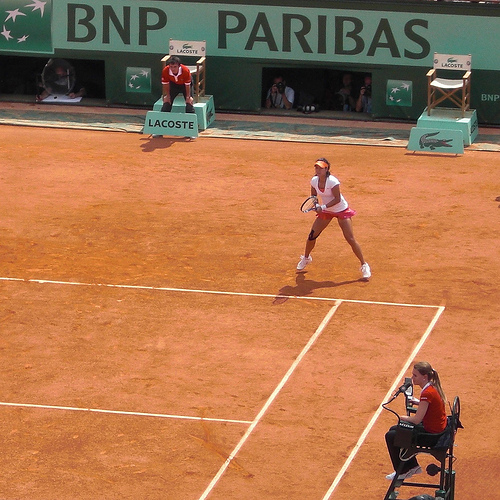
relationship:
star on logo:
[27, 2, 49, 17] [3, 5, 55, 52]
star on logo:
[4, 7, 22, 21] [3, 5, 55, 52]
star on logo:
[13, 35, 33, 45] [3, 5, 55, 52]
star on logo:
[1, 27, 12, 41] [3, 5, 55, 52]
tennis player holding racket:
[295, 157, 371, 280] [297, 195, 322, 213]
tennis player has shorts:
[295, 157, 371, 280] [315, 205, 355, 227]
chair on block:
[423, 47, 475, 113] [407, 99, 484, 154]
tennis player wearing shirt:
[295, 157, 371, 280] [311, 175, 348, 212]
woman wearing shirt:
[379, 357, 461, 482] [407, 384, 445, 436]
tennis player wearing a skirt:
[295, 157, 371, 280] [315, 208, 353, 222]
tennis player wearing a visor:
[295, 157, 371, 280] [312, 155, 324, 167]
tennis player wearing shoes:
[295, 157, 371, 280] [279, 240, 395, 286]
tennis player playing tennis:
[295, 157, 371, 280] [24, 134, 403, 413]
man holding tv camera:
[30, 57, 90, 104] [48, 67, 73, 91]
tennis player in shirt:
[294, 158, 371, 280] [311, 175, 349, 214]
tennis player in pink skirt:
[294, 158, 371, 280] [313, 206, 355, 221]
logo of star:
[0, 1, 58, 60] [23, 0, 49, 18]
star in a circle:
[23, 0, 49, 18] [0, 5, 59, 50]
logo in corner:
[0, 1, 58, 60] [5, 7, 66, 93]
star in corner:
[23, 0, 49, 18] [5, 7, 66, 93]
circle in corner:
[0, 5, 59, 50] [5, 7, 66, 93]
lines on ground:
[287, 285, 454, 343] [152, 163, 263, 262]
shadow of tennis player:
[272, 270, 369, 305] [295, 157, 371, 280]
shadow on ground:
[272, 270, 369, 305] [0, 122, 498, 498]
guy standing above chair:
[138, 40, 269, 130] [131, 94, 222, 141]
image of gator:
[404, 116, 461, 148] [411, 134, 468, 155]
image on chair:
[404, 116, 461, 148] [413, 53, 479, 160]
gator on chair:
[411, 134, 468, 155] [413, 53, 479, 160]